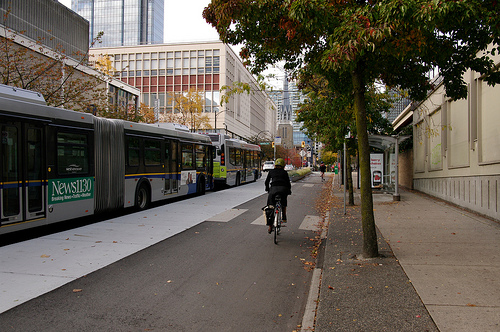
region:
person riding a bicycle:
[263, 157, 295, 245]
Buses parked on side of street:
[1, 97, 263, 244]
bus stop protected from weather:
[338, 122, 400, 208]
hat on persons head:
[272, 157, 287, 171]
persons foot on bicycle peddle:
[276, 212, 292, 227]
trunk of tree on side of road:
[352, 106, 379, 258]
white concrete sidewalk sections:
[375, 207, 498, 323]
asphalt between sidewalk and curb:
[317, 262, 403, 328]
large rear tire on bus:
[132, 177, 154, 214]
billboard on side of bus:
[48, 177, 96, 206]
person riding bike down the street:
[219, 135, 311, 295]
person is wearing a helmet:
[258, 148, 290, 179]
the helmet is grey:
[257, 144, 297, 176]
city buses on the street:
[7, 85, 276, 252]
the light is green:
[252, 134, 309, 148]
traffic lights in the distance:
[252, 125, 319, 173]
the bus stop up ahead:
[319, 117, 414, 238]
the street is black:
[158, 242, 283, 326]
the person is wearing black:
[240, 142, 310, 243]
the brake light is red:
[267, 200, 292, 217]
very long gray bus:
[1, 83, 222, 241]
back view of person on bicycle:
[254, 147, 297, 245]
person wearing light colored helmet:
[261, 148, 295, 243]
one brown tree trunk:
[348, 74, 382, 264]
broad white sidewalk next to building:
[378, 178, 498, 329]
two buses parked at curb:
[3, 68, 261, 238]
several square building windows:
[128, 37, 230, 126]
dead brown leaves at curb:
[303, 180, 340, 305]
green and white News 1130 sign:
[49, 170, 96, 208]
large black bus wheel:
[131, 171, 153, 213]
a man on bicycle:
[261, 157, 293, 240]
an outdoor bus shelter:
[367, 127, 408, 198]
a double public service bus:
[2, 80, 212, 238]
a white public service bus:
[208, 129, 263, 189]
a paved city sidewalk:
[317, 163, 499, 329]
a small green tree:
[199, 0, 499, 257]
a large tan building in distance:
[90, 43, 280, 143]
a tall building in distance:
[72, 0, 164, 46]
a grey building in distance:
[0, 0, 91, 62]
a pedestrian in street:
[317, 161, 328, 181]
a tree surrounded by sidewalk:
[201, 0, 499, 263]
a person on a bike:
[263, 155, 298, 245]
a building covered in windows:
[87, 49, 278, 139]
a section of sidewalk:
[369, 168, 496, 329]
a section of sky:
[162, 0, 287, 93]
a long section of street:
[0, 160, 325, 329]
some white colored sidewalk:
[1, 173, 265, 310]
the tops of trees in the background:
[1, 13, 215, 133]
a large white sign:
[364, 146, 387, 191]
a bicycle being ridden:
[262, 200, 284, 240]